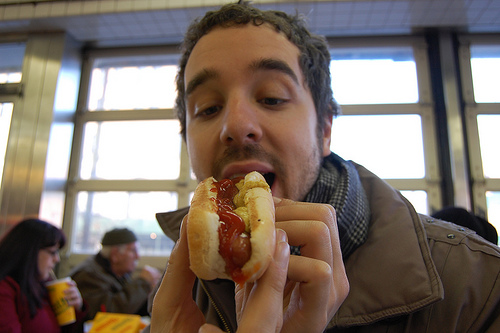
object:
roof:
[0, 0, 499, 73]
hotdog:
[218, 183, 252, 265]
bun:
[185, 175, 227, 280]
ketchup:
[207, 179, 262, 290]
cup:
[44, 275, 76, 325]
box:
[87, 311, 151, 333]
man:
[62, 224, 164, 333]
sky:
[0, 56, 499, 235]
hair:
[174, 0, 339, 162]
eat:
[224, 171, 272, 191]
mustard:
[231, 179, 249, 233]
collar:
[95, 250, 113, 273]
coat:
[62, 250, 156, 326]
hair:
[0, 216, 68, 323]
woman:
[0, 217, 83, 333]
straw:
[49, 270, 58, 282]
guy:
[146, 0, 500, 333]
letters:
[53, 300, 62, 309]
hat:
[427, 206, 498, 247]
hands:
[233, 196, 351, 333]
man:
[148, 0, 500, 332]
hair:
[99, 244, 128, 259]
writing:
[108, 317, 130, 330]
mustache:
[209, 143, 287, 183]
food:
[184, 169, 278, 289]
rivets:
[446, 233, 456, 239]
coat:
[138, 159, 500, 333]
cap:
[100, 226, 138, 247]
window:
[327, 43, 421, 106]